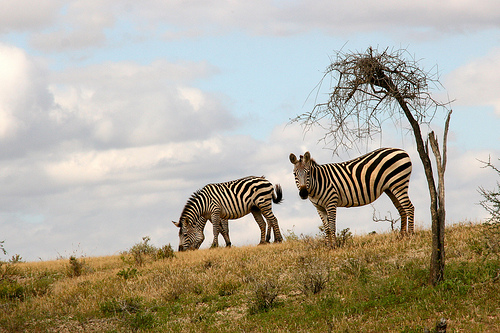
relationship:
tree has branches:
[341, 43, 461, 294] [337, 60, 392, 110]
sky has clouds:
[239, 74, 275, 107] [86, 66, 179, 148]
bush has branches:
[471, 150, 499, 252] [484, 214, 500, 231]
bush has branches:
[471, 150, 499, 252] [337, 60, 392, 110]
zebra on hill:
[279, 127, 417, 242] [45, 237, 144, 302]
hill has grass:
[45, 237, 144, 302] [318, 276, 397, 324]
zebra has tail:
[279, 127, 417, 242] [269, 183, 285, 199]